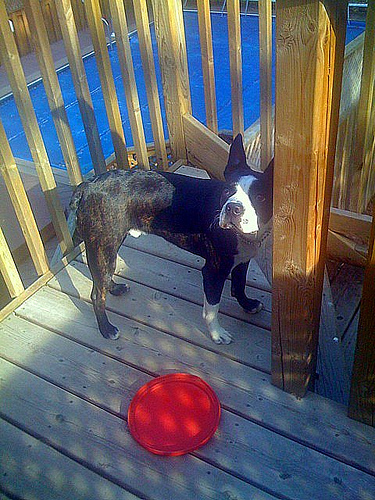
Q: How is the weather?
A: Sunny.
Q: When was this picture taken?
A: Daytime.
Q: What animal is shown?
A: A dog.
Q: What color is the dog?
A: Black and white.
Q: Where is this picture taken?
A: A deck.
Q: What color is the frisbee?
A: Red.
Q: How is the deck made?
A: Of wood.